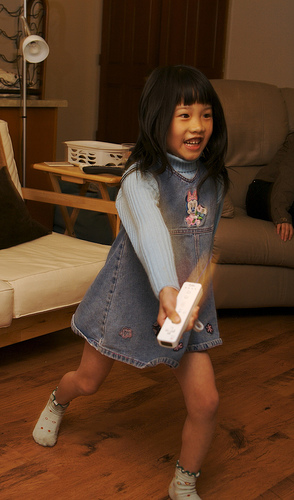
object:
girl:
[31, 64, 230, 500]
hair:
[121, 65, 231, 195]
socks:
[32, 385, 71, 449]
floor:
[0, 319, 293, 499]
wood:
[229, 382, 289, 470]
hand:
[157, 286, 200, 330]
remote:
[82, 164, 125, 176]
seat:
[0, 118, 114, 348]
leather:
[0, 232, 113, 328]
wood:
[16, 322, 36, 342]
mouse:
[185, 190, 208, 229]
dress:
[71, 140, 231, 371]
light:
[22, 35, 50, 65]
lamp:
[16, 14, 51, 187]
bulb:
[30, 42, 40, 57]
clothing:
[114, 154, 223, 302]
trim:
[51, 384, 71, 408]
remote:
[156, 281, 203, 350]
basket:
[64, 140, 133, 166]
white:
[21, 246, 63, 301]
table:
[31, 161, 120, 238]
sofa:
[210, 74, 292, 310]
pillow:
[0, 165, 52, 250]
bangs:
[171, 76, 212, 106]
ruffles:
[175, 478, 197, 496]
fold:
[45, 180, 120, 234]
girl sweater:
[114, 152, 223, 303]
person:
[245, 130, 294, 243]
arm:
[269, 135, 294, 220]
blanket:
[219, 189, 235, 218]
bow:
[187, 189, 198, 201]